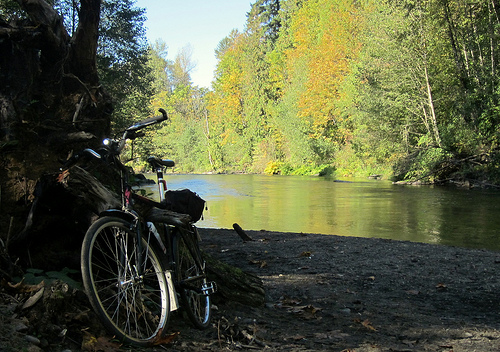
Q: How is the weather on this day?
A: It is clear.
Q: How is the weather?
A: It is clear.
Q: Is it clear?
A: Yes, it is clear.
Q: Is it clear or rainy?
A: It is clear.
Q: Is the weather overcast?
A: No, it is clear.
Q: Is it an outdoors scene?
A: Yes, it is outdoors.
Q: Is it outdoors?
A: Yes, it is outdoors.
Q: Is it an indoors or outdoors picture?
A: It is outdoors.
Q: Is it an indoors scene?
A: No, it is outdoors.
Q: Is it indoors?
A: No, it is outdoors.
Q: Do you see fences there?
A: No, there are no fences.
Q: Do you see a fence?
A: No, there are no fences.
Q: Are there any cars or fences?
A: No, there are no fences or cars.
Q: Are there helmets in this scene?
A: No, there are no helmets.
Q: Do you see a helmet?
A: No, there are no helmets.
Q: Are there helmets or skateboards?
A: No, there are no helmets or skateboards.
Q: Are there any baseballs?
A: No, there are no baseballs.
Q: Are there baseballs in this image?
A: No, there are no baseballs.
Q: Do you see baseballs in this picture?
A: No, there are no baseballs.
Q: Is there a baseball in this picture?
A: No, there are no baseballs.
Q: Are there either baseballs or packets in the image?
A: No, there are no baseballs or packets.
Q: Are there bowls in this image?
A: No, there are no bowls.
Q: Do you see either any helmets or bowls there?
A: No, there are no bowls or helmets.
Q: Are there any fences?
A: No, there are no fences.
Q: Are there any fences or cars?
A: No, there are no fences or cars.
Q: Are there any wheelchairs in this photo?
A: No, there are no wheelchairs.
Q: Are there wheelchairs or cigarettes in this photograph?
A: No, there are no wheelchairs or cigarettes.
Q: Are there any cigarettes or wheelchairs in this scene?
A: No, there are no wheelchairs or cigarettes.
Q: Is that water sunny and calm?
A: Yes, the water is sunny and calm.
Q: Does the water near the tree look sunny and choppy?
A: No, the water is sunny but calm.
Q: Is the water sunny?
A: Yes, the water is sunny.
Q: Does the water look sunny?
A: Yes, the water is sunny.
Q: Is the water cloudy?
A: No, the water is sunny.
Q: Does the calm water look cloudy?
A: No, the water is sunny.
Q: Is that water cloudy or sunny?
A: The water is sunny.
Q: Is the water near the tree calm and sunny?
A: Yes, the water is calm and sunny.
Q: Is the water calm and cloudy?
A: No, the water is calm but sunny.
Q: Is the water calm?
A: Yes, the water is calm.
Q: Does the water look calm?
A: Yes, the water is calm.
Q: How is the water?
A: The water is calm.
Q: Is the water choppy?
A: No, the water is calm.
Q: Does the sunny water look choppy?
A: No, the water is calm.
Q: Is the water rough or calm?
A: The water is calm.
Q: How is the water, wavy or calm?
A: The water is calm.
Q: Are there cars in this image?
A: No, there are no cars.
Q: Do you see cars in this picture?
A: No, there are no cars.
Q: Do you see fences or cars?
A: No, there are no cars or fences.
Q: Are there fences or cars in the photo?
A: No, there are no cars or fences.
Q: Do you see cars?
A: No, there are no cars.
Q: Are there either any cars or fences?
A: No, there are no cars or fences.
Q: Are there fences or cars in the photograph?
A: No, there are no cars or fences.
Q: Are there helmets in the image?
A: No, there are no helmets.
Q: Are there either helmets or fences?
A: No, there are no helmets or fences.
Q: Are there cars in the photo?
A: No, there are no cars.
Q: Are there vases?
A: No, there are no vases.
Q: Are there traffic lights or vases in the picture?
A: No, there are no vases or traffic lights.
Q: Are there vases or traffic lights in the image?
A: No, there are no vases or traffic lights.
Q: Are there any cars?
A: No, there are no cars.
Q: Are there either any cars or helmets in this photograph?
A: No, there are no cars or helmets.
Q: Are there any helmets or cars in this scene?
A: No, there are no cars or helmets.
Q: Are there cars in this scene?
A: No, there are no cars.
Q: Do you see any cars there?
A: No, there are no cars.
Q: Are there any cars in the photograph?
A: No, there are no cars.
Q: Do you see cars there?
A: No, there are no cars.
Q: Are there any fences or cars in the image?
A: No, there are no cars or fences.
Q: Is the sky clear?
A: Yes, the sky is clear.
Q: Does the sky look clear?
A: Yes, the sky is clear.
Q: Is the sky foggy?
A: No, the sky is clear.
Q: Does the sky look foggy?
A: No, the sky is clear.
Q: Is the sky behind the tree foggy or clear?
A: The sky is clear.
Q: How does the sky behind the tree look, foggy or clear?
A: The sky is clear.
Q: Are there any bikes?
A: Yes, there is a bike.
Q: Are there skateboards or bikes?
A: Yes, there is a bike.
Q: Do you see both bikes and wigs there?
A: No, there is a bike but no wigs.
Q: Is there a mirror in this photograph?
A: No, there are no mirrors.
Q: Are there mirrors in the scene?
A: No, there are no mirrors.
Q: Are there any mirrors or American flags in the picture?
A: No, there are no mirrors or American flags.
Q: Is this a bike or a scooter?
A: This is a bike.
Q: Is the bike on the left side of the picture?
A: Yes, the bike is on the left of the image.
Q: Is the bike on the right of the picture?
A: No, the bike is on the left of the image.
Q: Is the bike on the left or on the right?
A: The bike is on the left of the image.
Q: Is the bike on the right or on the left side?
A: The bike is on the left of the image.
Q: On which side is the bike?
A: The bike is on the left of the image.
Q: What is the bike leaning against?
A: The bike is leaning against the tree.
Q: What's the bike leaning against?
A: The bike is leaning against the tree.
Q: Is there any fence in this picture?
A: No, there are no fences.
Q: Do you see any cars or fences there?
A: No, there are no fences or cars.